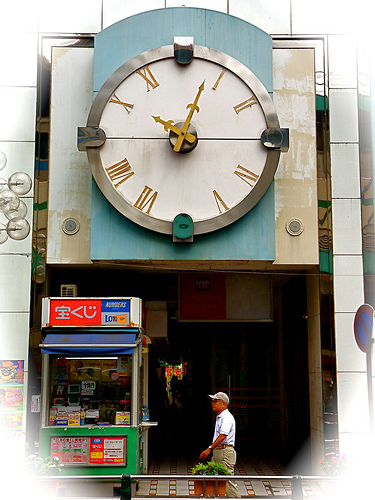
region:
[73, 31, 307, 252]
large decorative timepiece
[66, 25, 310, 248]
oversized time telling device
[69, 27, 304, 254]
clock indicating it was after ten in the morning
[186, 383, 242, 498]
man wearing white collared shirt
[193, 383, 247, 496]
man wearing khaki pants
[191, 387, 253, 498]
man wearing cap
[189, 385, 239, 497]
man wearing gold wristwatch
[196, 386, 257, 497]
man wearing dark sunglasses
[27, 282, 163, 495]
large colorful vendor stand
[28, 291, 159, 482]
green red and blue newsstand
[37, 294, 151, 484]
the shop cart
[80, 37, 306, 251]
the clock above the entrance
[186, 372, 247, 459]
the man is walking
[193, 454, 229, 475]
the potted plants beside the man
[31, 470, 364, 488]
the railing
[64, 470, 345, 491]
the railing is metal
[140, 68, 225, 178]
the hands of the clock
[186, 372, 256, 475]
the man wearing the tan cap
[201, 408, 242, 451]
the man wearing the blue shirt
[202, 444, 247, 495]
the man wearing tan pants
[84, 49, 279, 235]
A clock.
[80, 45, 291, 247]
The clock face is white.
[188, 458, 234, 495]
A potted plant.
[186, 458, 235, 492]
The plant is green.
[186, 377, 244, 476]
A person is walking.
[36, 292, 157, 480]
A stand.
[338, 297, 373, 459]
A street sign is to the right.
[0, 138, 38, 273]
A street light is to the left.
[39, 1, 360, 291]
The clock is on a building.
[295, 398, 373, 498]
The picture has a white border.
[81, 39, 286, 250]
a large silver and white clock face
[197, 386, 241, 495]
a pedestrian walking sidewalk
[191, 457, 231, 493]
a potted green plant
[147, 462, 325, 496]
a red and white sidewalk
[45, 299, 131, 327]
a business promotional sign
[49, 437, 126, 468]
a business promotional sign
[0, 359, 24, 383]
a business promotional sign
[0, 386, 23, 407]
a business promotional sign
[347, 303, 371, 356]
a street traffic sign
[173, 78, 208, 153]
a clock minute hand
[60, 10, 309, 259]
a big round clock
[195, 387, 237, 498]
a man in a tan cap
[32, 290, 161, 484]
a green and blue kiosk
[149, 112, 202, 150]
the clock's hour hand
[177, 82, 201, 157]
the clock's minute hand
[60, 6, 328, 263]
a clock with Roman numerals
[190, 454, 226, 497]
flower box hanging off the handrail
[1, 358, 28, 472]
colorful posters on the wall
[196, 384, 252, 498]
a man wearing khaki pants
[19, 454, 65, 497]
white box of flowers